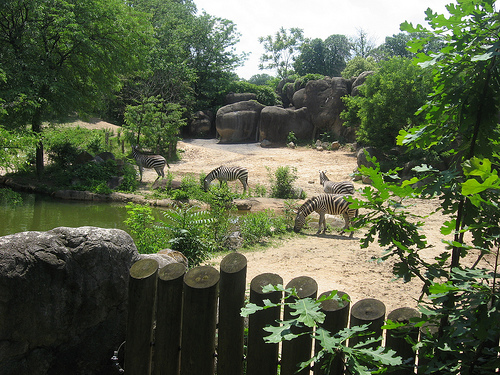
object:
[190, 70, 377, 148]
rock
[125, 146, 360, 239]
animals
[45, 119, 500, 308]
dirt enclosure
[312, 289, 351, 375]
fence post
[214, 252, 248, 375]
post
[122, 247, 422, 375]
cut logs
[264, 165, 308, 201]
bush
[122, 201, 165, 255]
bush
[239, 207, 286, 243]
bush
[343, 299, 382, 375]
post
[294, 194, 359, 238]
zebra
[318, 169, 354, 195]
zebra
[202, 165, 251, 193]
zebra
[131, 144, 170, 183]
zebra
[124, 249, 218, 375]
fence posts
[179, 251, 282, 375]
fence posts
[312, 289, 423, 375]
fence posts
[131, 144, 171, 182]
giraffe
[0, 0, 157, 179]
tree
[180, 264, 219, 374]
post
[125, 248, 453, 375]
fence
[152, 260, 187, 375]
post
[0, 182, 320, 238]
pond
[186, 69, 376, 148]
rock wall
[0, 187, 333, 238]
water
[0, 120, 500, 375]
dirt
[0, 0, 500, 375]
zoo